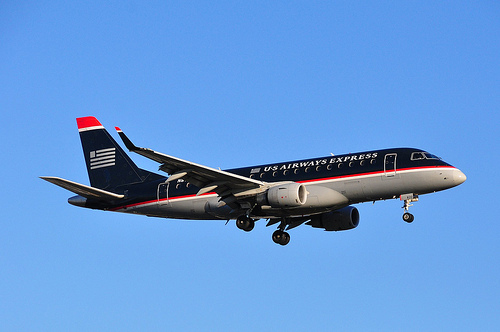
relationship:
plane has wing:
[64, 108, 473, 241] [129, 145, 256, 185]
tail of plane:
[61, 109, 141, 198] [64, 108, 473, 241]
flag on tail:
[73, 137, 125, 175] [61, 109, 141, 198]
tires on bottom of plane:
[240, 208, 308, 256] [64, 108, 473, 241]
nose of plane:
[440, 150, 471, 194] [64, 108, 473, 241]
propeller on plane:
[252, 182, 311, 208] [64, 108, 473, 241]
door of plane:
[373, 148, 401, 189] [64, 108, 473, 241]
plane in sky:
[64, 108, 473, 241] [262, 22, 354, 41]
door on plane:
[373, 148, 401, 189] [64, 108, 473, 241]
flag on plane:
[73, 137, 125, 175] [64, 108, 473, 241]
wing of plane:
[129, 145, 256, 185] [64, 108, 473, 241]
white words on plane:
[264, 158, 382, 171] [64, 108, 473, 241]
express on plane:
[330, 153, 386, 162] [64, 108, 473, 241]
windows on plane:
[260, 170, 384, 182] [64, 108, 473, 241]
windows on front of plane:
[404, 140, 447, 163] [64, 108, 473, 241]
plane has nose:
[64, 108, 473, 241] [440, 150, 471, 194]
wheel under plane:
[392, 193, 421, 221] [64, 108, 473, 241]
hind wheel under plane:
[233, 208, 291, 249] [64, 108, 473, 241]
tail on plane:
[61, 109, 141, 198] [64, 108, 473, 241]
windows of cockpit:
[404, 140, 447, 163] [401, 132, 458, 175]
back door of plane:
[155, 177, 174, 208] [64, 108, 473, 241]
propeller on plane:
[262, 175, 311, 212] [39, 115, 469, 247]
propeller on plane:
[308, 201, 363, 231] [39, 115, 469, 247]